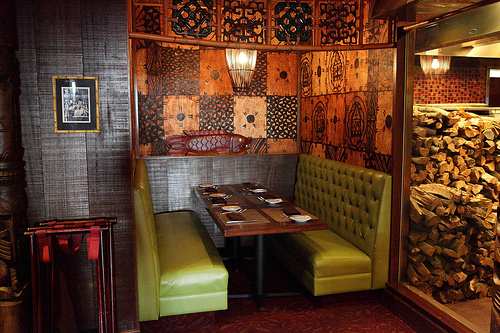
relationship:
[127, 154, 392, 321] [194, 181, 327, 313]
booth at table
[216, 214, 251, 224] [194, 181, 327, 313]
silverware on table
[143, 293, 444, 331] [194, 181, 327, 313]
carpet under table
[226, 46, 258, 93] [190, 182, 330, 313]
light above table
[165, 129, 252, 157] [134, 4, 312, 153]
fish on wall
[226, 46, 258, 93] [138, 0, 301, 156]
light on wall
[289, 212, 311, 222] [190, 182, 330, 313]
plate on table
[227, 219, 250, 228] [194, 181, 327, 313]
utensils on top of table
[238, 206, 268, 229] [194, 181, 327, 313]
placemat on table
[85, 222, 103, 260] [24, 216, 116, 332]
stands to hold tray holder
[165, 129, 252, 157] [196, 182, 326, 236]
fish next to table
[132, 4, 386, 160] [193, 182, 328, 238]
wallpaper in booth